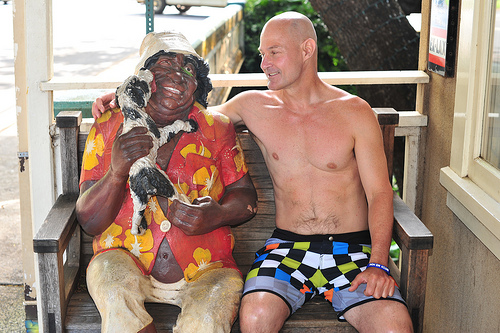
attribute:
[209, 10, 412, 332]
man — shirtless, sitting, tying, smiling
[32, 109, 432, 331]
bench — on a porch, brown, wooden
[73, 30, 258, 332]
statue — smiling, black, a man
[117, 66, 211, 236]
dog — beautiful, black, white, statue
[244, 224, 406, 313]
swim trunks — multicolored, colorful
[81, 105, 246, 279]
hawaiian shirt — red, yellow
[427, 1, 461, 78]
board — displaying info, mounted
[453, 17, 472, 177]
frame — yellow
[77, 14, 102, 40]
handle — invisible